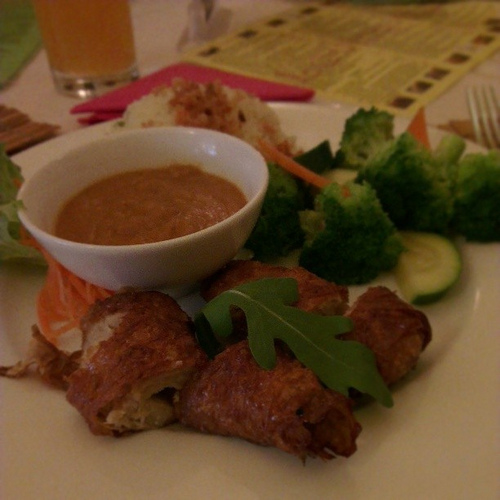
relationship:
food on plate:
[32, 117, 444, 416] [365, 261, 495, 488]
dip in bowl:
[69, 170, 217, 241] [32, 144, 245, 270]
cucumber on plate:
[394, 226, 467, 301] [365, 261, 495, 488]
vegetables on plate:
[284, 124, 488, 288] [365, 261, 495, 488]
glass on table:
[36, 0, 144, 106] [130, 3, 392, 97]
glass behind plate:
[36, 0, 144, 106] [365, 261, 495, 488]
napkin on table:
[110, 47, 288, 111] [130, 3, 392, 97]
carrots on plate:
[30, 261, 107, 331] [365, 261, 495, 488]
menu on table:
[218, 6, 485, 109] [130, 3, 392, 97]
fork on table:
[463, 80, 499, 156] [130, 3, 392, 97]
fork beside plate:
[463, 80, 499, 156] [365, 261, 495, 488]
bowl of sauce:
[32, 144, 245, 270] [69, 170, 217, 241]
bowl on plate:
[32, 144, 245, 270] [365, 261, 495, 488]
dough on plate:
[84, 306, 283, 430] [365, 261, 495, 488]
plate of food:
[443, 294, 496, 488] [32, 117, 444, 416]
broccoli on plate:
[327, 137, 445, 247] [365, 261, 495, 488]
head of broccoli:
[325, 176, 403, 265] [327, 137, 445, 247]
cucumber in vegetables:
[394, 226, 467, 301] [284, 124, 488, 288]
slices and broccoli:
[30, 261, 107, 331] [327, 137, 445, 247]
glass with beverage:
[36, 0, 144, 106] [47, 6, 126, 72]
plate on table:
[365, 261, 495, 488] [130, 3, 392, 97]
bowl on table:
[32, 144, 245, 270] [130, 3, 392, 97]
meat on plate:
[84, 306, 283, 430] [365, 261, 495, 488]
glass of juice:
[36, 0, 144, 106] [47, 6, 126, 72]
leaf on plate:
[221, 277, 379, 388] [365, 261, 495, 488]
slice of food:
[394, 226, 467, 301] [32, 117, 444, 416]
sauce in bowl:
[69, 170, 217, 241] [32, 144, 245, 270]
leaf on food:
[221, 277, 379, 388] [32, 117, 444, 416]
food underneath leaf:
[32, 117, 444, 416] [221, 277, 379, 388]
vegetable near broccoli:
[394, 226, 467, 301] [327, 137, 445, 247]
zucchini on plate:
[394, 226, 467, 301] [365, 261, 495, 488]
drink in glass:
[47, 6, 126, 72] [36, 0, 144, 106]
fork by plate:
[463, 80, 499, 156] [443, 294, 496, 488]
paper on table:
[218, 6, 485, 109] [130, 3, 392, 97]